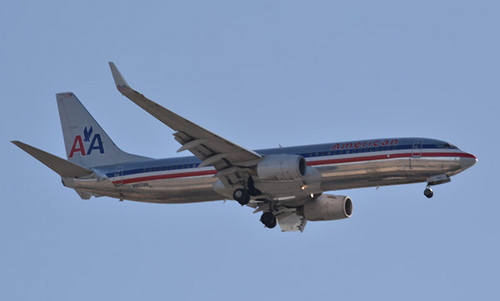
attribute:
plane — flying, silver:
[9, 60, 477, 230]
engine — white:
[255, 151, 310, 186]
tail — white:
[56, 96, 167, 188]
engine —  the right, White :
[280, 191, 369, 230]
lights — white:
[298, 183, 320, 200]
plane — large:
[33, 44, 498, 250]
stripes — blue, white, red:
[106, 145, 468, 185]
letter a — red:
[65, 132, 85, 159]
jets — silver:
[30, 41, 499, 246]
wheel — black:
[413, 180, 441, 200]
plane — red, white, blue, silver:
[31, 103, 398, 275]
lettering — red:
[66, 123, 107, 158]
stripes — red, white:
[104, 149, 474, 186]